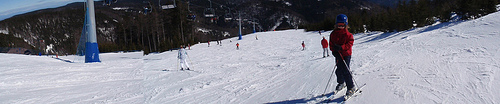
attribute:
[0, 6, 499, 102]
slope — busy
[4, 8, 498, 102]
snow — thick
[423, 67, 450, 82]
ground — suitable for weather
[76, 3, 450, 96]
winter — beautiful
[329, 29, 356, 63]
ski jacket — warm, suitable for weather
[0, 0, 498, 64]
mountains — beautiful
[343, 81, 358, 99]
boot — ski boot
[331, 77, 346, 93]
boot — ski boot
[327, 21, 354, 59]
jacket — ski jacket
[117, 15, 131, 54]
tree — distant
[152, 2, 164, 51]
tree — distant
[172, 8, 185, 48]
tree — distant